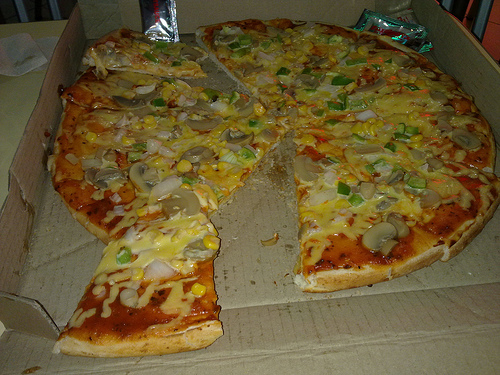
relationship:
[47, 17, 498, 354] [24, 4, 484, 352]
pizza in a box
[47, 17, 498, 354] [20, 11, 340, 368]
pizza in a box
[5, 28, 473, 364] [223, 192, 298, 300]
pizza on cardboard